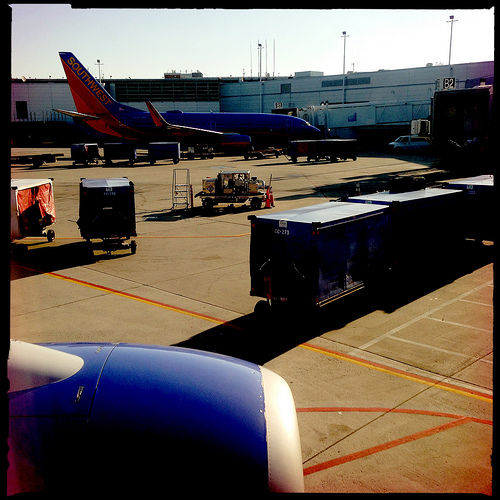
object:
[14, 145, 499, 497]
ground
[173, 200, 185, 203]
stairs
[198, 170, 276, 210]
tractor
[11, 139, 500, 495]
road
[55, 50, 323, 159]
plane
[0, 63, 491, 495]
airport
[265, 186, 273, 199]
person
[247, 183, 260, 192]
orange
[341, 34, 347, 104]
pole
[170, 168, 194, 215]
ladder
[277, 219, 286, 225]
sign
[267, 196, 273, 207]
cone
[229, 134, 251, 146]
engine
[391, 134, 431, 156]
van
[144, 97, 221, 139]
wing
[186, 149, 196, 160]
wheel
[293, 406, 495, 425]
line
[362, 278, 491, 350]
line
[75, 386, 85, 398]
number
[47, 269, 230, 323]
line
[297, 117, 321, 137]
nose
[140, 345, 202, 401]
color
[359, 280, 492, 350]
paint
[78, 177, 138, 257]
truck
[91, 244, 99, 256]
wheels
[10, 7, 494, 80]
sky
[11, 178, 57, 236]
tarp